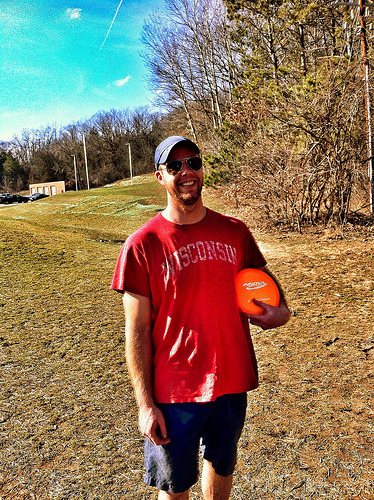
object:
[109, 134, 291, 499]
man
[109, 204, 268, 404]
shirt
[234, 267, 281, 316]
frisbee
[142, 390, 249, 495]
shorts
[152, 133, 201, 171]
cap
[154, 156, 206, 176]
sunglasses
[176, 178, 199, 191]
smile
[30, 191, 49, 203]
cars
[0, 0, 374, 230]
background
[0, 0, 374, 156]
sky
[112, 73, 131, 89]
cloud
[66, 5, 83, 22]
cloud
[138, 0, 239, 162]
woods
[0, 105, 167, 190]
woods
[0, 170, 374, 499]
field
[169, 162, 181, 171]
eyes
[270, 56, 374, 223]
bush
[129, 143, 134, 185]
poles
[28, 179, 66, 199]
building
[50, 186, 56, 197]
doors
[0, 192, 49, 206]
lot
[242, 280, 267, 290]
words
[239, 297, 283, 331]
hand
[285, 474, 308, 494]
branch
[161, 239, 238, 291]
words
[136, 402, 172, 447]
hand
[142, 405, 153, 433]
veins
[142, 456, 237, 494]
edge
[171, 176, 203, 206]
beard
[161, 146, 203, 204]
face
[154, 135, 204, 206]
head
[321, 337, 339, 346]
sticks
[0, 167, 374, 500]
dirt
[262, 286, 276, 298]
orange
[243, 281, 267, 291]
white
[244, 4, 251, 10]
leaves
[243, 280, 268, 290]
fluorescent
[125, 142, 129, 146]
light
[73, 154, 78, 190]
pole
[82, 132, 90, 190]
pole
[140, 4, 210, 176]
tree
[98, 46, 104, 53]
airplane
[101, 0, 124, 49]
exhaust